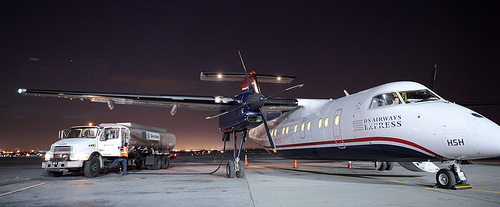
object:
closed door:
[331, 109, 348, 149]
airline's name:
[363, 114, 403, 130]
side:
[245, 79, 500, 188]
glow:
[171, 139, 226, 152]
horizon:
[1, 135, 267, 152]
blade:
[198, 49, 298, 94]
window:
[334, 114, 339, 126]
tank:
[116, 123, 175, 155]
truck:
[40, 122, 177, 178]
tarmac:
[0, 142, 500, 207]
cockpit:
[358, 81, 452, 122]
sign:
[145, 131, 161, 141]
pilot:
[391, 97, 400, 105]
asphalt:
[0, 180, 497, 207]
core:
[246, 93, 266, 108]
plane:
[17, 80, 500, 188]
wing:
[16, 88, 336, 112]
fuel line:
[208, 141, 227, 175]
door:
[98, 125, 124, 158]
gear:
[433, 165, 469, 188]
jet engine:
[199, 71, 304, 134]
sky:
[361, 20, 442, 57]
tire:
[84, 152, 102, 178]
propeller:
[16, 70, 301, 150]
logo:
[363, 115, 402, 131]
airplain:
[18, 49, 500, 191]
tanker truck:
[39, 122, 175, 178]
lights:
[2, 144, 234, 158]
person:
[106, 142, 131, 176]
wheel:
[435, 166, 468, 188]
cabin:
[332, 79, 456, 131]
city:
[167, 140, 239, 157]